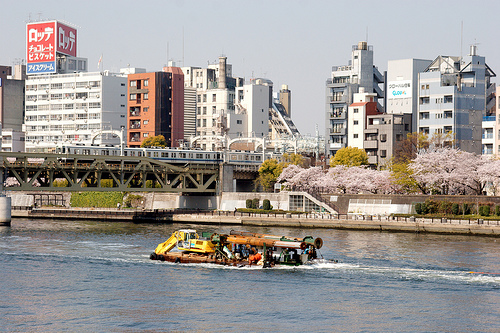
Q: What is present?
A: Buildings.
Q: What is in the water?
A: A boat.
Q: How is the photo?
A: Clear.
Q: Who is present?
A: Nobody.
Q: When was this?
A: Daytime.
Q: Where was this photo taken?
A: At a river.